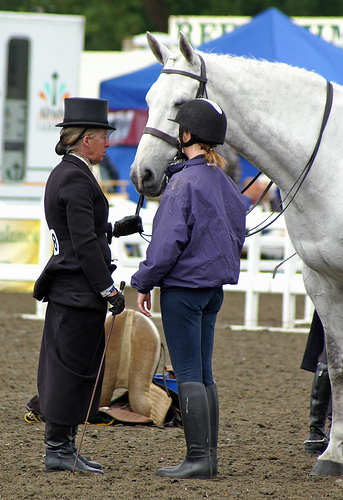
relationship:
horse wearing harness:
[165, 60, 339, 159] [285, 80, 338, 162]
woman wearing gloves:
[41, 91, 125, 439] [104, 288, 125, 314]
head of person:
[45, 86, 123, 166] [29, 70, 125, 237]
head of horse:
[129, 29, 203, 198] [129, 27, 343, 477]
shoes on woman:
[37, 418, 111, 477] [41, 97, 125, 475]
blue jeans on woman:
[159, 282, 224, 381] [130, 98, 248, 478]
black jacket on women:
[30, 153, 113, 310] [129, 98, 247, 480]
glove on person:
[104, 289, 128, 315] [45, 87, 132, 211]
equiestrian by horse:
[157, 103, 245, 315] [122, 20, 340, 257]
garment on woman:
[37, 156, 126, 474] [36, 95, 140, 460]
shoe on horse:
[307, 457, 342, 475] [129, 27, 343, 477]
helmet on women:
[170, 100, 236, 149] [129, 98, 247, 480]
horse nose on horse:
[125, 159, 162, 190] [129, 27, 343, 477]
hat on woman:
[52, 92, 116, 131] [28, 92, 142, 474]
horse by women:
[129, 27, 343, 477] [32, 97, 247, 478]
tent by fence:
[89, 8, 342, 171] [10, 188, 317, 334]